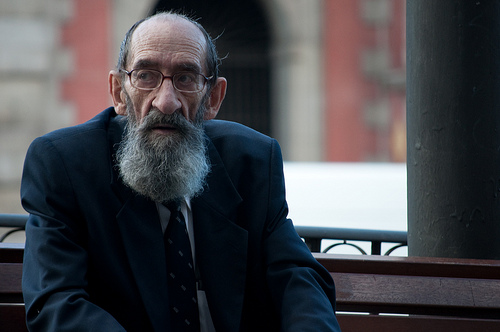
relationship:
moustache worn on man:
[111, 107, 213, 203] [20, 13, 341, 331]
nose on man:
[152, 79, 182, 114] [20, 13, 341, 331]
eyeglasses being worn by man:
[119, 68, 215, 93] [20, 13, 341, 331]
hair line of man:
[129, 11, 208, 40] [20, 13, 341, 331]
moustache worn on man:
[136, 110, 201, 134] [20, 13, 341, 331]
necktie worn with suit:
[163, 196, 199, 330] [20, 105, 343, 331]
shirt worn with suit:
[155, 191, 216, 331] [20, 105, 343, 331]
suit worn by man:
[20, 105, 343, 331] [20, 13, 341, 331]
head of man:
[120, 12, 217, 139] [20, 13, 341, 331]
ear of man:
[107, 70, 128, 116] [20, 13, 341, 331]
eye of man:
[140, 74, 156, 82] [20, 13, 341, 331]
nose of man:
[152, 79, 182, 114] [20, 13, 341, 331]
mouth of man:
[146, 122, 182, 135] [20, 13, 341, 331]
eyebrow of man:
[133, 58, 161, 71] [20, 13, 341, 331]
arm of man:
[21, 136, 124, 330] [20, 13, 341, 331]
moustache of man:
[111, 107, 213, 203] [20, 13, 341, 331]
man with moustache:
[20, 13, 341, 331] [111, 107, 213, 203]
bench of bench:
[0, 245, 499, 331] [0, 241, 499, 331]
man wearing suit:
[20, 13, 341, 331] [20, 105, 343, 331]